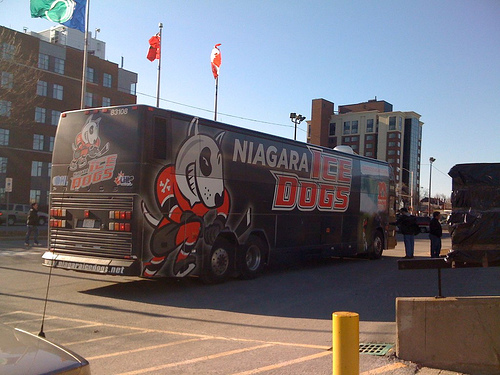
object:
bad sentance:
[127, 0, 415, 177]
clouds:
[281, 23, 387, 83]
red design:
[210, 43, 222, 80]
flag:
[146, 22, 164, 108]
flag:
[30, 0, 90, 109]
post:
[332, 311, 361, 374]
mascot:
[140, 117, 231, 279]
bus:
[41, 104, 398, 285]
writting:
[232, 139, 353, 212]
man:
[385, 207, 422, 259]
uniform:
[149, 164, 232, 258]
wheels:
[205, 237, 234, 285]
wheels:
[365, 230, 385, 260]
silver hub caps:
[211, 247, 229, 277]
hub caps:
[374, 237, 383, 252]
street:
[0, 252, 399, 374]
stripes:
[0, 311, 406, 375]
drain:
[358, 342, 394, 356]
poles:
[81, 0, 90, 108]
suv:
[1, 204, 49, 226]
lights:
[289, 112, 306, 124]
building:
[0, 28, 142, 204]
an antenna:
[36, 165, 70, 338]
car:
[1, 321, 92, 375]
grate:
[358, 341, 389, 357]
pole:
[294, 123, 297, 141]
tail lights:
[108, 210, 131, 231]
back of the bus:
[42, 103, 144, 278]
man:
[24, 202, 42, 247]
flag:
[210, 43, 223, 120]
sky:
[0, 0, 499, 199]